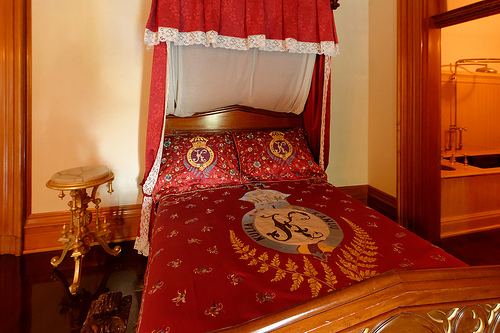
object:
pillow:
[151, 130, 246, 202]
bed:
[135, 101, 496, 332]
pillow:
[230, 128, 329, 184]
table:
[43, 163, 124, 297]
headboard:
[157, 104, 307, 137]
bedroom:
[2, 1, 499, 333]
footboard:
[192, 263, 498, 332]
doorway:
[414, 2, 500, 274]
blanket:
[135, 178, 472, 332]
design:
[181, 135, 219, 180]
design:
[266, 130, 298, 167]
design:
[220, 185, 384, 299]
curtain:
[134, 0, 340, 260]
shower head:
[476, 65, 498, 73]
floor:
[0, 251, 56, 331]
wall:
[29, 2, 402, 213]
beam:
[425, 1, 500, 33]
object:
[73, 289, 138, 332]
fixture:
[445, 58, 500, 152]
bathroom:
[430, 1, 498, 235]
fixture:
[463, 153, 468, 166]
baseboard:
[19, 203, 140, 255]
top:
[46, 165, 113, 187]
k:
[259, 211, 325, 242]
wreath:
[226, 214, 381, 301]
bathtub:
[439, 151, 498, 238]